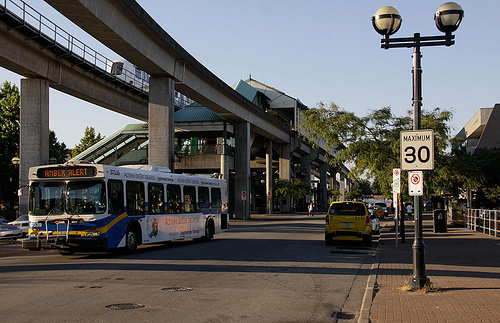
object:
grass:
[402, 277, 432, 297]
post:
[409, 28, 426, 293]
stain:
[208, 309, 232, 322]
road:
[1, 209, 372, 322]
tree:
[302, 99, 500, 242]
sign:
[399, 129, 435, 170]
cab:
[325, 200, 373, 249]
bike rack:
[44, 214, 70, 239]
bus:
[30, 161, 231, 254]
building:
[60, 73, 348, 215]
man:
[405, 201, 415, 221]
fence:
[3, 0, 152, 96]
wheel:
[126, 227, 140, 251]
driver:
[78, 185, 98, 215]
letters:
[39, 166, 89, 176]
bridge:
[1, 0, 289, 207]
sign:
[266, 191, 273, 201]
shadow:
[261, 209, 327, 223]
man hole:
[162, 283, 192, 294]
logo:
[149, 216, 160, 238]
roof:
[171, 101, 217, 124]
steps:
[73, 122, 147, 165]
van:
[374, 197, 387, 215]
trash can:
[432, 209, 446, 233]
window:
[106, 178, 126, 213]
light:
[372, 3, 461, 49]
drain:
[334, 308, 355, 322]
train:
[106, 57, 150, 92]